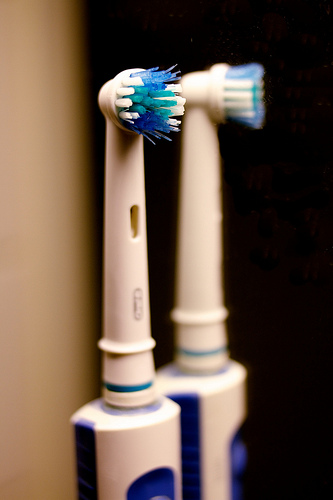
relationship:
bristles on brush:
[108, 71, 198, 138] [90, 35, 178, 390]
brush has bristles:
[90, 35, 178, 390] [108, 71, 198, 138]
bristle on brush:
[240, 96, 259, 107] [90, 35, 178, 390]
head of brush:
[63, 68, 197, 162] [90, 35, 178, 390]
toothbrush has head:
[54, 53, 191, 499] [63, 68, 197, 162]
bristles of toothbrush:
[108, 71, 198, 138] [54, 53, 191, 499]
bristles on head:
[108, 71, 198, 138] [63, 68, 197, 162]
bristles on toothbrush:
[108, 71, 198, 138] [54, 53, 191, 499]